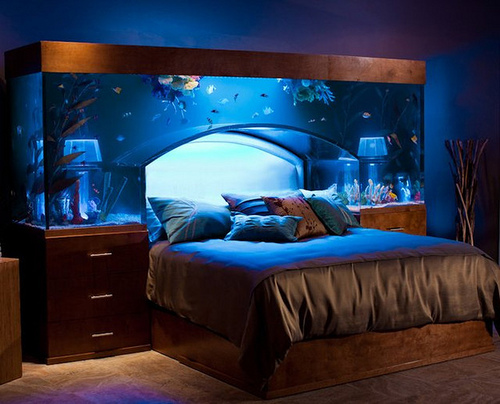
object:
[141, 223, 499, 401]
bed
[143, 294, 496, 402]
frame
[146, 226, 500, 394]
blanket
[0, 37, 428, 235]
aquarium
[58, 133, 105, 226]
left lamp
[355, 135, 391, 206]
right lamp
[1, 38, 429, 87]
wood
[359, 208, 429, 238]
right drawers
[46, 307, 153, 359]
left drawers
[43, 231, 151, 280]
drawers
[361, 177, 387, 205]
coral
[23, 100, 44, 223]
plants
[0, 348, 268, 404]
floor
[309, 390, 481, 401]
carpet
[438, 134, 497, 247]
plant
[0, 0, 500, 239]
wall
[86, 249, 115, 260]
handles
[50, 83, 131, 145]
water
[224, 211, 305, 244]
pillow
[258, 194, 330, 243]
pillow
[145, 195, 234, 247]
pillow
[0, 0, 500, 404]
bedroom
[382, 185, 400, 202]
fish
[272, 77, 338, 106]
coral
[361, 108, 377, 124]
fish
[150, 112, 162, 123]
fish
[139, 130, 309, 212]
headboard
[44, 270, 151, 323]
dresser drawer